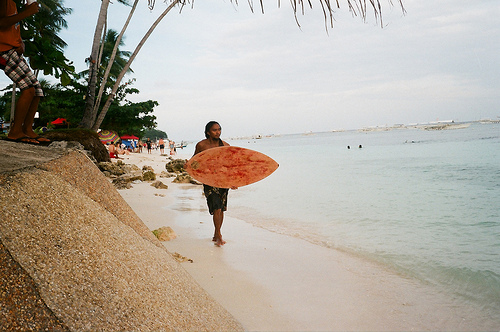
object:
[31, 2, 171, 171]
palm tree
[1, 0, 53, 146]
man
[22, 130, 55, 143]
foot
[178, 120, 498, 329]
water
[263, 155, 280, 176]
tip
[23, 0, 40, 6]
cup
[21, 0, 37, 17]
hand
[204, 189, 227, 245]
leg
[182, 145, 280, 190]
board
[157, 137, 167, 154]
group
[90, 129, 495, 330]
beach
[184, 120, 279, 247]
man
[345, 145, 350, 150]
head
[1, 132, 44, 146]
feet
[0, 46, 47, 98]
shorts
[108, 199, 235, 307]
rocks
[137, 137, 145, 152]
people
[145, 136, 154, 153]
man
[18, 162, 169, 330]
boulder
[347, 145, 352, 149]
man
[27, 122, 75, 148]
shade